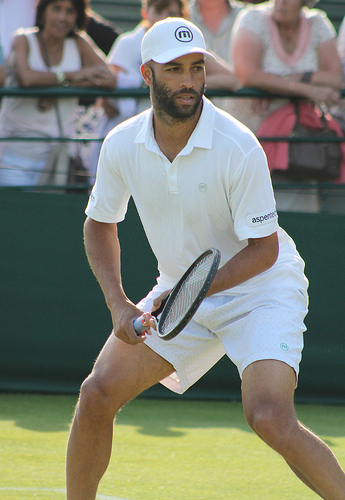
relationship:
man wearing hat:
[119, 14, 290, 254] [136, 11, 222, 66]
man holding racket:
[119, 14, 290, 254] [159, 256, 239, 337]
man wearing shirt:
[119, 14, 290, 254] [112, 125, 280, 254]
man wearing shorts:
[119, 14, 290, 254] [178, 367, 252, 412]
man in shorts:
[119, 14, 290, 254] [178, 367, 252, 412]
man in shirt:
[119, 14, 290, 254] [112, 125, 280, 254]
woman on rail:
[19, 6, 109, 86] [25, 90, 65, 101]